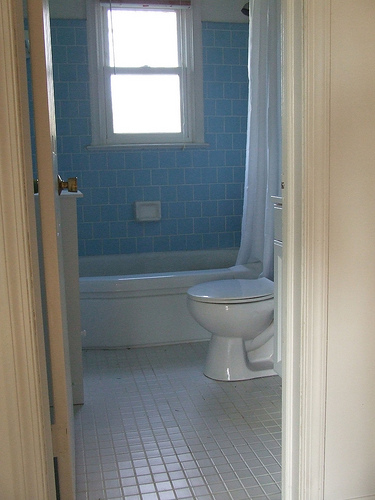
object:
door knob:
[57, 174, 77, 196]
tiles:
[74, 339, 282, 498]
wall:
[23, 0, 249, 256]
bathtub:
[78, 248, 261, 353]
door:
[28, 1, 76, 499]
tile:
[207, 47, 222, 63]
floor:
[73, 341, 282, 500]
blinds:
[107, 7, 179, 69]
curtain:
[234, 0, 281, 281]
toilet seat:
[186, 297, 274, 306]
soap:
[139, 204, 160, 219]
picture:
[109, 6, 182, 137]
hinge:
[44, 424, 67, 458]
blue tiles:
[59, 64, 77, 81]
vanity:
[270, 196, 284, 378]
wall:
[301, 0, 375, 500]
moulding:
[302, 0, 331, 500]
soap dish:
[135, 198, 161, 221]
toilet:
[187, 278, 278, 383]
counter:
[34, 190, 83, 198]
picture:
[1, 0, 369, 498]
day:
[108, 8, 181, 132]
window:
[94, 2, 195, 145]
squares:
[50, 342, 283, 500]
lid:
[187, 277, 274, 303]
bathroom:
[25, 3, 283, 500]